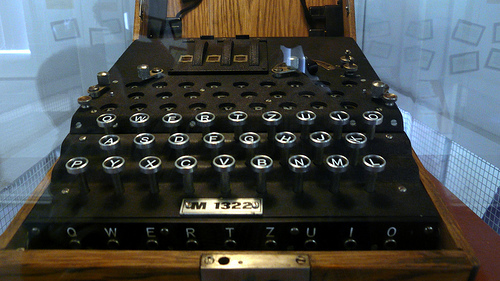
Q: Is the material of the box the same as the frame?
A: Yes, both the box and the frame are made of wood.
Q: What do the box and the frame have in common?
A: The material, both the box and the frame are wooden.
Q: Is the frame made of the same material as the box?
A: Yes, both the frame and the box are made of wood.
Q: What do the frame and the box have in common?
A: The material, both the frame and the box are wooden.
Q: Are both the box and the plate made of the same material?
A: No, the box is made of wood and the plate is made of metal.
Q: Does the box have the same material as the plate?
A: No, the box is made of wood and the plate is made of metal.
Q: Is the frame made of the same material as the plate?
A: No, the frame is made of wood and the plate is made of metal.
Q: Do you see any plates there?
A: Yes, there is a plate.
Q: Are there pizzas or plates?
A: Yes, there is a plate.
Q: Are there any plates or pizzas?
A: Yes, there is a plate.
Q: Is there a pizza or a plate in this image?
A: Yes, there is a plate.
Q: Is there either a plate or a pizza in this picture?
A: Yes, there is a plate.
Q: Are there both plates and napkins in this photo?
A: No, there is a plate but no napkins.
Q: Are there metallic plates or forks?
A: Yes, there is a metal plate.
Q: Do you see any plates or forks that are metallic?
A: Yes, the plate is metallic.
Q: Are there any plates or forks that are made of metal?
A: Yes, the plate is made of metal.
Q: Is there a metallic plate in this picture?
A: Yes, there is a metal plate.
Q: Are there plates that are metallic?
A: Yes, there is a plate that is metallic.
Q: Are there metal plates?
A: Yes, there is a plate that is made of metal.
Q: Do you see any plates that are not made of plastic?
A: Yes, there is a plate that is made of metal.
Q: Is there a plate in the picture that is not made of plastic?
A: Yes, there is a plate that is made of metal.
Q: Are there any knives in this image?
A: No, there are no knives.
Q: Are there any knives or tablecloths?
A: No, there are no knives or tablecloths.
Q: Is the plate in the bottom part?
A: Yes, the plate is in the bottom of the image.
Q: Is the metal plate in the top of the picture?
A: No, the plate is in the bottom of the image.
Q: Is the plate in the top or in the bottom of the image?
A: The plate is in the bottom of the image.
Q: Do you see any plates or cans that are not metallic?
A: No, there is a plate but it is metallic.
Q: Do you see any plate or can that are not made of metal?
A: No, there is a plate but it is made of metal.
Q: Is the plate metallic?
A: Yes, the plate is metallic.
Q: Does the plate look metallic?
A: Yes, the plate is metallic.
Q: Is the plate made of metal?
A: Yes, the plate is made of metal.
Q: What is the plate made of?
A: The plate is made of metal.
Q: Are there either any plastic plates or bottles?
A: No, there is a plate but it is metallic.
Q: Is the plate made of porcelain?
A: No, the plate is made of metal.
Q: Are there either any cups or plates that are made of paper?
A: No, there is a plate but it is made of metal.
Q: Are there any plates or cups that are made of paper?
A: No, there is a plate but it is made of metal.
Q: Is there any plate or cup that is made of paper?
A: No, there is a plate but it is made of metal.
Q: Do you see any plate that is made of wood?
A: No, there is a plate but it is made of metal.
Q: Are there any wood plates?
A: No, there is a plate but it is made of metal.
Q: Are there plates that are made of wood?
A: No, there is a plate but it is made of metal.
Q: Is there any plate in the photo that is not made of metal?
A: No, there is a plate but it is made of metal.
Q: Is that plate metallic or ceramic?
A: The plate is metallic.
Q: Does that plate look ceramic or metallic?
A: The plate is metallic.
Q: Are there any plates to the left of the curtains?
A: Yes, there is a plate to the left of the curtains.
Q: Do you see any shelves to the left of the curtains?
A: No, there is a plate to the left of the curtains.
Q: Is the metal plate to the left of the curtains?
A: Yes, the plate is to the left of the curtains.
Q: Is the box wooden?
A: Yes, the box is wooden.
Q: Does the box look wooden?
A: Yes, the box is wooden.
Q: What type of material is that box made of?
A: The box is made of wood.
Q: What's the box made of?
A: The box is made of wood.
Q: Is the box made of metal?
A: No, the box is made of wood.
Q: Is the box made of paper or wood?
A: The box is made of wood.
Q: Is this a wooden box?
A: Yes, this is a wooden box.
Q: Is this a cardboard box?
A: No, this is a wooden box.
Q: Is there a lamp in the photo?
A: No, there are no lamps.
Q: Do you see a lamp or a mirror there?
A: No, there are no lamps or mirrors.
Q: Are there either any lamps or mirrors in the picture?
A: No, there are no lamps or mirrors.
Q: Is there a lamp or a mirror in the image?
A: No, there are no lamps or mirrors.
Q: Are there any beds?
A: No, there are no beds.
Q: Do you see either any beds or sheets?
A: No, there are no beds or sheets.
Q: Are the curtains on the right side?
A: Yes, the curtains are on the right of the image.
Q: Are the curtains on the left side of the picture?
A: No, the curtains are on the right of the image.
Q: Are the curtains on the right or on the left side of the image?
A: The curtains are on the right of the image.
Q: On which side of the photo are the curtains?
A: The curtains are on the right of the image.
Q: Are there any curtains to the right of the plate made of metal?
A: Yes, there are curtains to the right of the plate.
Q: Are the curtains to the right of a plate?
A: Yes, the curtains are to the right of a plate.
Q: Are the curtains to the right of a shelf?
A: No, the curtains are to the right of a plate.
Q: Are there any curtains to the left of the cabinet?
A: No, the curtains are to the right of the cabinet.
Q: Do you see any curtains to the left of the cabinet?
A: No, the curtains are to the right of the cabinet.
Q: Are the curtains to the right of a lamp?
A: No, the curtains are to the right of the cabinet.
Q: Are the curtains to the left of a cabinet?
A: No, the curtains are to the right of a cabinet.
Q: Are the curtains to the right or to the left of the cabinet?
A: The curtains are to the right of the cabinet.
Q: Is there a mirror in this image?
A: No, there are no mirrors.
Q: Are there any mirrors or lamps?
A: No, there are no mirrors or lamps.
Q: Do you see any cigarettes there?
A: No, there are no cigarettes.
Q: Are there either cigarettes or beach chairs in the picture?
A: No, there are no cigarettes or beach chairs.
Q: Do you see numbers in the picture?
A: Yes, there are numbers.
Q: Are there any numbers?
A: Yes, there are numbers.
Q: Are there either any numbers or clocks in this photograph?
A: Yes, there are numbers.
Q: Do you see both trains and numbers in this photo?
A: No, there are numbers but no trains.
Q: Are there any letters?
A: Yes, there are letters.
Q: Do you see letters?
A: Yes, there are letters.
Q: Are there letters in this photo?
A: Yes, there are letters.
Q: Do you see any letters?
A: Yes, there are letters.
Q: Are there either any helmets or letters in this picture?
A: Yes, there are letters.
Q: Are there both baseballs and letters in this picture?
A: No, there are letters but no baseballs.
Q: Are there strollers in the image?
A: No, there are no strollers.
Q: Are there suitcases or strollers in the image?
A: No, there are no strollers or suitcases.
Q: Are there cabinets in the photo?
A: Yes, there is a cabinet.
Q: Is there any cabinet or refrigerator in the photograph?
A: Yes, there is a cabinet.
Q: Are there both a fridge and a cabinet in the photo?
A: No, there is a cabinet but no refrigerators.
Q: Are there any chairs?
A: No, there are no chairs.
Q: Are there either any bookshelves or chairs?
A: No, there are no chairs or bookshelves.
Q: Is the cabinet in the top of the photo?
A: Yes, the cabinet is in the top of the image.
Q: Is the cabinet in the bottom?
A: No, the cabinet is in the top of the image.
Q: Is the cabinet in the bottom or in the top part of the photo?
A: The cabinet is in the top of the image.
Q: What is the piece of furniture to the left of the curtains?
A: The piece of furniture is a cabinet.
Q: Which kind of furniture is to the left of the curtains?
A: The piece of furniture is a cabinet.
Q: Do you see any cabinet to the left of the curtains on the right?
A: Yes, there is a cabinet to the left of the curtains.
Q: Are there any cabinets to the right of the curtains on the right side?
A: No, the cabinet is to the left of the curtains.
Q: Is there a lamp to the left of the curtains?
A: No, there is a cabinet to the left of the curtains.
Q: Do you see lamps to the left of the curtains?
A: No, there is a cabinet to the left of the curtains.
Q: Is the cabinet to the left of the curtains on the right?
A: Yes, the cabinet is to the left of the curtains.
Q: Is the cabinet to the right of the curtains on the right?
A: No, the cabinet is to the left of the curtains.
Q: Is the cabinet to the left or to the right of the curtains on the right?
A: The cabinet is to the left of the curtains.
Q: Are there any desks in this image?
A: Yes, there is a desk.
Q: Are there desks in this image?
A: Yes, there is a desk.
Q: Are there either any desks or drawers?
A: Yes, there is a desk.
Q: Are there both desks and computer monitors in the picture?
A: No, there is a desk but no computer monitors.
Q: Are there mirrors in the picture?
A: No, there are no mirrors.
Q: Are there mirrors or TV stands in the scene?
A: No, there are no mirrors or TV stands.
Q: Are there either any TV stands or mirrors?
A: No, there are no mirrors or TV stands.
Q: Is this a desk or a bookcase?
A: This is a desk.